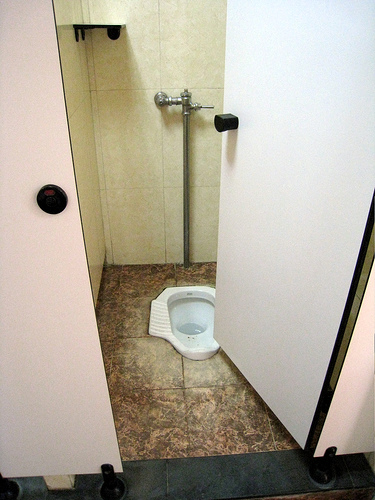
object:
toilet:
[143, 286, 220, 356]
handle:
[192, 102, 217, 114]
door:
[210, 3, 373, 456]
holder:
[74, 23, 124, 46]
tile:
[120, 388, 187, 457]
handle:
[211, 116, 239, 132]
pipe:
[182, 106, 193, 276]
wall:
[84, 47, 153, 244]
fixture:
[152, 89, 177, 110]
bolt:
[34, 185, 71, 216]